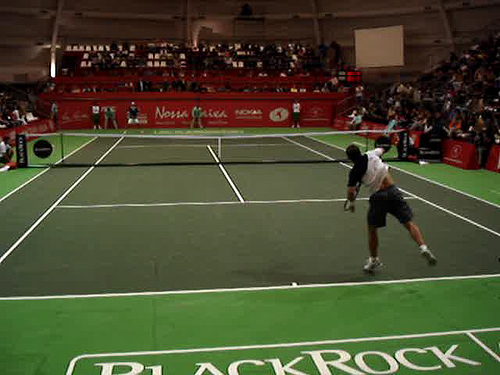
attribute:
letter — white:
[188, 358, 223, 373]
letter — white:
[356, 340, 387, 367]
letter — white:
[93, 357, 144, 373]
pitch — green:
[1, 126, 498, 373]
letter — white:
[293, 335, 348, 373]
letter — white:
[140, 364, 171, 372]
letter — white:
[266, 351, 306, 372]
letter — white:
[93, 361, 146, 372]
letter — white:
[147, 362, 170, 372]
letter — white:
[188, 356, 218, 372]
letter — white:
[265, 354, 301, 372]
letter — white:
[353, 349, 393, 372]